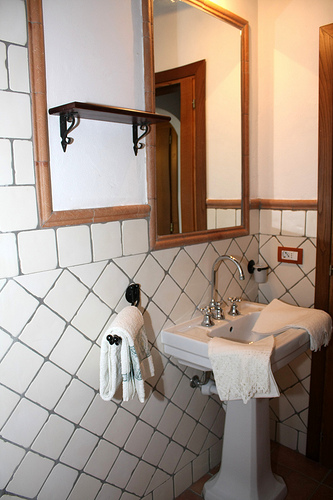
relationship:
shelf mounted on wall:
[47, 101, 171, 153] [1, 0, 257, 498]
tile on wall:
[17, 302, 68, 361] [1, 0, 257, 498]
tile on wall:
[52, 375, 98, 429] [1, 0, 257, 498]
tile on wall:
[24, 412, 75, 465] [1, 0, 257, 498]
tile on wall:
[100, 405, 137, 451] [1, 0, 257, 498]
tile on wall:
[16, 229, 58, 273] [1, 0, 257, 498]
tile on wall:
[17, 302, 68, 361] [255, 0, 321, 455]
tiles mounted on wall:
[66, 406, 142, 484] [1, 0, 257, 498]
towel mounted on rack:
[99, 305, 154, 400] [107, 284, 140, 346]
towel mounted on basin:
[251, 295, 331, 349] [207, 309, 289, 344]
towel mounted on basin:
[208, 335, 280, 401] [207, 309, 289, 344]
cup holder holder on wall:
[256, 252, 268, 291] [253, 19, 318, 309]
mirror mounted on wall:
[141, 0, 250, 253] [1, 0, 257, 498]